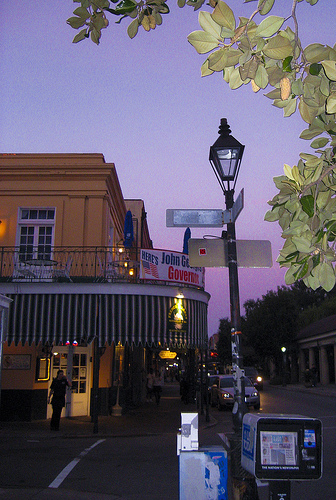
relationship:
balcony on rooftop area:
[2, 244, 208, 291] [0, 151, 206, 287]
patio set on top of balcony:
[6, 245, 140, 281] [2, 244, 208, 291]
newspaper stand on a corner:
[236, 410, 325, 500] [171, 410, 335, 500]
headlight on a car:
[221, 393, 234, 402] [208, 373, 261, 409]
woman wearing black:
[46, 367, 73, 435] [48, 377, 71, 431]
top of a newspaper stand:
[176, 409, 202, 457] [172, 410, 232, 500]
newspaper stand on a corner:
[172, 410, 232, 500] [171, 410, 335, 500]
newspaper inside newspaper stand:
[261, 431, 299, 468] [236, 410, 325, 500]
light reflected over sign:
[176, 290, 186, 329] [162, 302, 191, 334]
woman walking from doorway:
[46, 367, 73, 435] [44, 330, 95, 424]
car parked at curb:
[208, 373, 261, 409] [178, 377, 217, 430]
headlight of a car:
[249, 390, 261, 400] [208, 373, 261, 409]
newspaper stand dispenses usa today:
[236, 410, 325, 500] [261, 431, 299, 468]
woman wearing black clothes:
[46, 367, 73, 435] [48, 377, 71, 431]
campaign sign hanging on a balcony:
[138, 249, 207, 292] [2, 244, 208, 291]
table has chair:
[23, 256, 60, 281] [48, 248, 78, 283]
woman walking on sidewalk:
[46, 367, 73, 435] [0, 375, 220, 441]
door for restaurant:
[47, 346, 95, 418] [1, 152, 221, 440]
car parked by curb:
[205, 374, 215, 389] [178, 377, 217, 430]